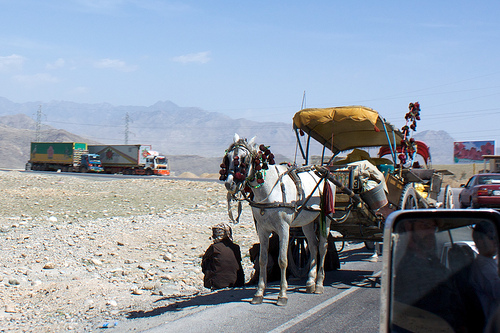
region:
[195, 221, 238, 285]
a man waiting in the desert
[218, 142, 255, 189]
the white horses head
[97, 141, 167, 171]
the white truck in the distance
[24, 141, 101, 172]
the blue and green truck in the distance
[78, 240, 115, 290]
the brown rocks on the side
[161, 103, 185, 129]
the misty mountians in the distance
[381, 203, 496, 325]
a mirror to a car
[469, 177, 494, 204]
the tail end of a red car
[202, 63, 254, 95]
the clear blue sky up above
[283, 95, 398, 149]
the man's brown carriage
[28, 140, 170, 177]
two trucks on the road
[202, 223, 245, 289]
person sitting on the side of the road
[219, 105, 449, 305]
horse drawn carriage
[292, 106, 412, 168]
tan canopy over the carriage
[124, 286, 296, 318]
shadow of the horse on the ground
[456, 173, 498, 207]
small red compact car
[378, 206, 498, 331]
reflection of people in rear view mirror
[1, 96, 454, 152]
mountainous landscape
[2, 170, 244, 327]
gravel and rock covering the ground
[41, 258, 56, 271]
a rock on ground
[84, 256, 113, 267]
a rock on ground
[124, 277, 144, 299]
a rock on ground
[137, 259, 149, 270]
a rock on ground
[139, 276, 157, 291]
a rock on ground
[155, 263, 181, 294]
a rock on ground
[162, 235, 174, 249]
a rock on ground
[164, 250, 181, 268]
a rock on ground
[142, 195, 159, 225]
a rock on ground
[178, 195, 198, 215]
a rock on ground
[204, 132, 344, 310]
the horse is white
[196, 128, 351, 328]
the horse is white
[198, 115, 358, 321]
the horse is white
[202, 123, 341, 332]
the horse is white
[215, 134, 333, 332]
the horse is white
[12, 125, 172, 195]
two trucks are visible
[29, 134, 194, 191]
two trucks are visible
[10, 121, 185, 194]
two trucks are visible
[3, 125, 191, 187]
two trucks are visible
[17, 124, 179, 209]
two trucks are visible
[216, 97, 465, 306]
Horse and cart on road.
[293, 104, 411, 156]
Canvas top on cart.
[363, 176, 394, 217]
Metal bucket hanging on side of cart.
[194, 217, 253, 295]
Person sitting on side of road.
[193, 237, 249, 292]
Person wearing brown jacket.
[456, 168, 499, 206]
Red car moving down road.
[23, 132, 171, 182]
Two trucks moving down road.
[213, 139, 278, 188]
Decoration over horse's head.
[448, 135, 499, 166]
Advertising sign in background.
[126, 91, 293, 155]
Mountains rising in background.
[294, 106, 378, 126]
the covering is brown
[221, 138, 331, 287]
the horse is white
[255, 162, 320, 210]
the straps are black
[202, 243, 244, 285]
the shirt is brown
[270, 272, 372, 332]
white line on the road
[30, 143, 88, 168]
green and yellow trailer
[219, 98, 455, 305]
a white horse pulling a wagon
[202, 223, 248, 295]
a person sitting on the ground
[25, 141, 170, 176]
trucks driving side by side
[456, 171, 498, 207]
red car is being driven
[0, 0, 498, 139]
sky is blue and partly cloudy